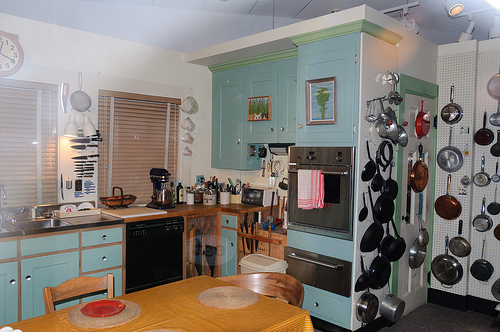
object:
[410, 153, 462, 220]
two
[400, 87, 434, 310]
on door.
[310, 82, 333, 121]
tree picture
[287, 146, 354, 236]
stove.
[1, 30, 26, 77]
clock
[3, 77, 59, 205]
window.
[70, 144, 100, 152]
knives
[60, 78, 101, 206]
wall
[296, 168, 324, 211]
towels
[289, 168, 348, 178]
stove handle.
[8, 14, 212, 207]
wall.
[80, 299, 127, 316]
red plate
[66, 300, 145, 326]
wicker placemat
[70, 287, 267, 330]
two woven placemats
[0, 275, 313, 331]
table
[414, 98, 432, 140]
red skillet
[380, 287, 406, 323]
soup pot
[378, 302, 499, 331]
floor.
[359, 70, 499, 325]
pots and pans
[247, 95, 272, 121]
artwork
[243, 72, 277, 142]
cabinet door.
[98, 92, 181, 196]
brown mini blinds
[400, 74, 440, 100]
wooden trim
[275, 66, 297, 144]
cabinets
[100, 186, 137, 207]
fruit basket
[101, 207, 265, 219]
counter.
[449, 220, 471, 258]
pans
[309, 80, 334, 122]
pictures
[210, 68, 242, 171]
blue cabinets.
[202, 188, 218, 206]
kitchen utensils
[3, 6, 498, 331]
photo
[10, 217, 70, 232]
sink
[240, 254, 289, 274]
trash can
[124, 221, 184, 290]
black dishwasher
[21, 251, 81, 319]
blue cabinets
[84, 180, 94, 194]
magnets.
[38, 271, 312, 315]
two chairs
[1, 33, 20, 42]
beige.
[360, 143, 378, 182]
black frying pans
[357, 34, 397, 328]
wall.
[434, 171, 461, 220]
pans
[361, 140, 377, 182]
pots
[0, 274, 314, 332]
cloth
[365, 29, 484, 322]
wall